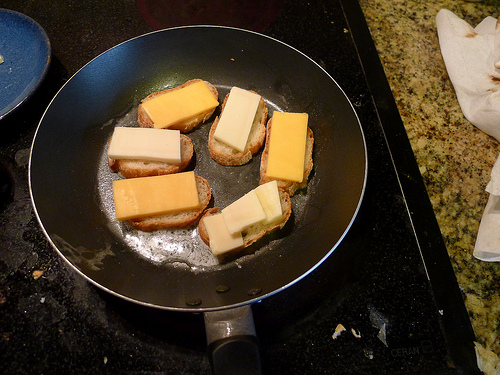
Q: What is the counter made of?
A: Marble.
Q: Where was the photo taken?
A: A kitchen.